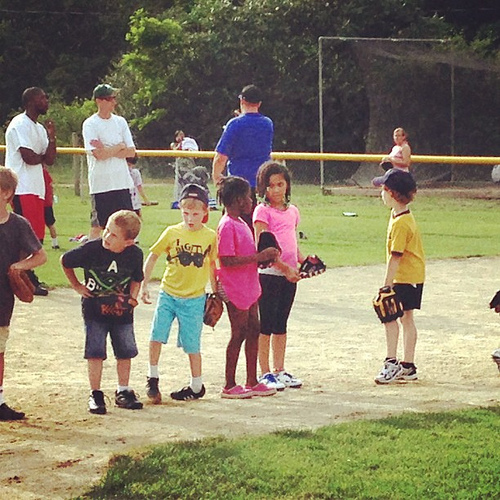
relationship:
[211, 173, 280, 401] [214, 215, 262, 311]
child wearing shirt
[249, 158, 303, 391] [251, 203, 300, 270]
child wearing shirt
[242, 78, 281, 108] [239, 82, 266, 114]
cap on head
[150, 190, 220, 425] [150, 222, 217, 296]
boy wearing jersey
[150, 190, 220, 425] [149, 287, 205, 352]
boy wearing shorts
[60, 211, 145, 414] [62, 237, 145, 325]
boy wearing t-shirt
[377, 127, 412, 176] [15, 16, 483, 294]
adult in background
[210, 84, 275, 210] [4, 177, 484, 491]
adult in playing field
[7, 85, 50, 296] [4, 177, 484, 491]
adult in playing field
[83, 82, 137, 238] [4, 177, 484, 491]
adult in playing field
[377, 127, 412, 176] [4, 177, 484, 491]
adult in playing field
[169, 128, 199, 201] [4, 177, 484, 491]
adult in playing field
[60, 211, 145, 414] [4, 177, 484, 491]
boy in playing field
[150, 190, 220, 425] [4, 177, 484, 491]
boy in playing field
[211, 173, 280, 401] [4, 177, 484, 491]
child in playing field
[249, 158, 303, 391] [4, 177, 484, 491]
child in playing field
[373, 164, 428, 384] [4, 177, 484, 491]
child in playing field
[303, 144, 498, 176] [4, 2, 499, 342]
pole across park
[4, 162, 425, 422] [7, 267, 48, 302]
children with gloves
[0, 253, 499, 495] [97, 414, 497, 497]
dirt path between area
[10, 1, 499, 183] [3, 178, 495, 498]
trees behind park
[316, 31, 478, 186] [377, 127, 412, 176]
metal frame behind adult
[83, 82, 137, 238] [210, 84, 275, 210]
adult listening to adult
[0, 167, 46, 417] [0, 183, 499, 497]
children standing on field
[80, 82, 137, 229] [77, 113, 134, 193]
adult wearing shirt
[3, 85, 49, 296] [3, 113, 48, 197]
adult wearing shirt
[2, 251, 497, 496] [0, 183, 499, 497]
dirt on field